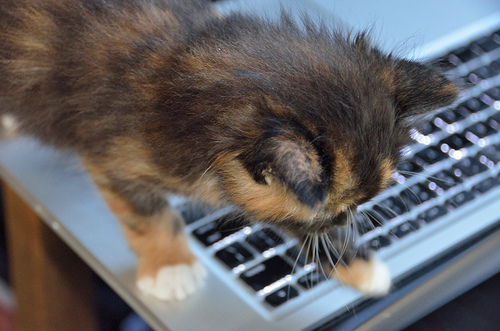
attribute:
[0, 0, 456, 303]
cat — brown, furry, black, standing, striped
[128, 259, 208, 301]
paw — white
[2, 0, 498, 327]
laptop — silver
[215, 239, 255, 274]
key — black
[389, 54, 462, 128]
ear — black, brown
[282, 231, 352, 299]
whiskers — white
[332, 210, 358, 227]
nose — black